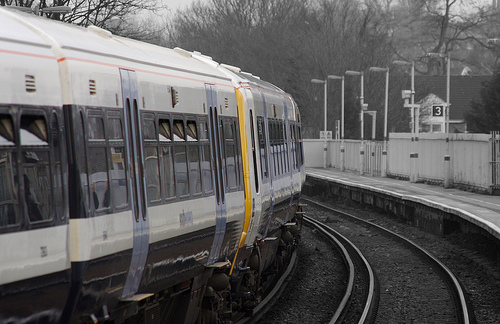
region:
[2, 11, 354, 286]
a passenger train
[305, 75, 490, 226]
a train stop with no people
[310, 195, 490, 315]
an empty rail way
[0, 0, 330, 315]
a white passenger train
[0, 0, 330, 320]
a train going around a curve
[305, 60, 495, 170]
a white fence and lamps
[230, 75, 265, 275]
a yellow and white train door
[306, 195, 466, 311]
metal train rails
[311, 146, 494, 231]
an empty train platform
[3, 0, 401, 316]
a train going past a train stop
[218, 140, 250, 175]
part of a window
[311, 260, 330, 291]
part of a ground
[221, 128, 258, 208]
part of a train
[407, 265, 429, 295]
part of a ground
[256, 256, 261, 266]
part of a metal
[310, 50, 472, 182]
light posts lining the tracks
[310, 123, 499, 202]
fence around the train tracks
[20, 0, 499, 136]
trees outside of the train tracks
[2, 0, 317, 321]
a train on the tracks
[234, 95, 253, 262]
yellow stripe on the train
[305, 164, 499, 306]
ledge by the train tracks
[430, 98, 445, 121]
a number on the sign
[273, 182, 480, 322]
train tracks on the ground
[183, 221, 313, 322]
wheels on the tracks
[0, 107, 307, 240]
windows on the train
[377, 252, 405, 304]
part of a ground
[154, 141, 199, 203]
part of a window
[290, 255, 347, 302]
part of a ground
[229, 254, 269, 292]
part of a wheel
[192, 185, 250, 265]
part of a train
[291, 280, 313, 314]
part of a ground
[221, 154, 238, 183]
part of a window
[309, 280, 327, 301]
part of a ground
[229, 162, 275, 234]
part of a train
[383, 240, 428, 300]
part of a ground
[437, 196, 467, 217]
edge of a ground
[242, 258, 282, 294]
part of a wheel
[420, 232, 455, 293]
edge of a rail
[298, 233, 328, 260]
part of a ground